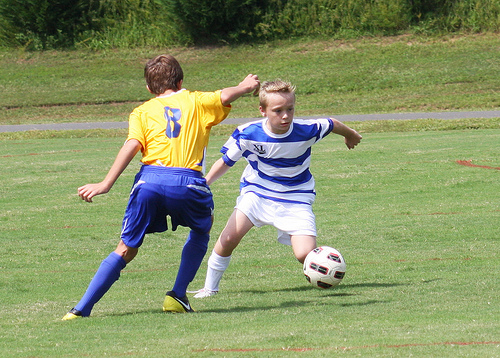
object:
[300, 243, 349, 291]
ball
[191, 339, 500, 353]
red stripe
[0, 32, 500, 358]
ground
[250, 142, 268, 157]
size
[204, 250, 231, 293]
sock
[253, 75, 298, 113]
blonde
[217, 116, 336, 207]
striped shirt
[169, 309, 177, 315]
right cleat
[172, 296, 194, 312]
nike swoosh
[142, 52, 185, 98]
hair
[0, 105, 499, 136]
walkway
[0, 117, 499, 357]
grass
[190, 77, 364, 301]
boy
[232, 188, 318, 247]
shorts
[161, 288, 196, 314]
shoe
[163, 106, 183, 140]
number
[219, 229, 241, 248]
knee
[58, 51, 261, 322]
boy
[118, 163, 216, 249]
shorts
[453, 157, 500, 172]
marking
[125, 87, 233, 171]
yellow shirt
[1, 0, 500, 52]
trees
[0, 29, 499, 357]
field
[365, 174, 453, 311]
air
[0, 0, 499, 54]
bunch